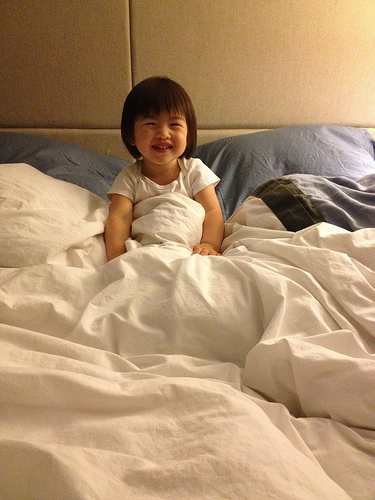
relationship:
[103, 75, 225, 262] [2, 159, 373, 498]
child under blanket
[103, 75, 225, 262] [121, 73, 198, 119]
child has hair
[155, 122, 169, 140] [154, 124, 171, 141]
nose on girl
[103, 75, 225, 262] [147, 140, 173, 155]
child has mouth